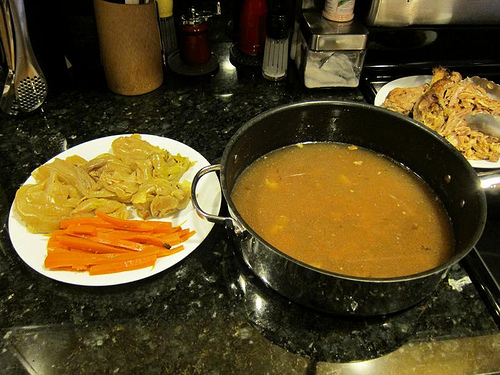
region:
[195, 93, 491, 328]
black pot of soup on counter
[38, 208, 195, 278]
cooked carrots on plate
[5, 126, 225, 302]
white plate of food on counter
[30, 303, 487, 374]
black granite counter top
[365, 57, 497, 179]
chicken on a plate on stove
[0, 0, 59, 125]
silver metal cooking utensils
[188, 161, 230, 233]
silver handle of black pot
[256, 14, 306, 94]
salt in a clear glass shaker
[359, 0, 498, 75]
back part of a silver stove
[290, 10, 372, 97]
glass container with silver lid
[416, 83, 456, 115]
cooked chicken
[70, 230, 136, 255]
cooked carrots on plate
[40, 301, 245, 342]
dark colored kitchen countertop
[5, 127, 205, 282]
white plate with cooked food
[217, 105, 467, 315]
cooking pan containing broth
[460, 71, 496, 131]
metal tongs resting on chicken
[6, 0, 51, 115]
spoon with drain holes in it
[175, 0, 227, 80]
pepper mill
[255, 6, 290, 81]
nearly empty salt shaker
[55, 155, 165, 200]
cooked cabbage on plate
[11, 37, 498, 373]
the counter top is black quartz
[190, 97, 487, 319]
a black pan is on the counter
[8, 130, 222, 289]
the plate of food is on the counter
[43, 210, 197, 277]
sliced carrots are on the plate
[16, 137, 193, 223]
cooked squash and cabbage are on the plate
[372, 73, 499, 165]
a plate of shredded chicken is on the counter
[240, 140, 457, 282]
chicken soup is in the pot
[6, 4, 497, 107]
condiments are behind the food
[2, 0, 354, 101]
utensils are behind the food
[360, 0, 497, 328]
the chicken is sitting on the stove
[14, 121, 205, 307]
cooked carrots and cabbage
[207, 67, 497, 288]
a pot of chicken stock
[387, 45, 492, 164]
pulled shredded chicken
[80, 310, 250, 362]
a black counter top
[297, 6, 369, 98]
a container of tea bags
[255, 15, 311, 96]
a glass salt shaker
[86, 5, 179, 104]
a container for kitchen utensils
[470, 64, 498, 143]
a set of kitchen tongs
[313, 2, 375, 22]
a jar of seasoning salt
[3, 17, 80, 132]
various kitchen utensils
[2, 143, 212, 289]
The plate is white.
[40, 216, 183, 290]
The carrot is orange.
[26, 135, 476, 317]
Food on the counter top.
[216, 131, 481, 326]
The black pot has chicken soup.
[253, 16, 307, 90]
The salt shaker is on the counter.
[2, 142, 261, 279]
Food is on the plate.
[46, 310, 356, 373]
The counter top is black marble.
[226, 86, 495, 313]
The pot is black.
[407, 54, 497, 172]
A plate of food.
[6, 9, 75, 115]
Cooking utensils are on the counter